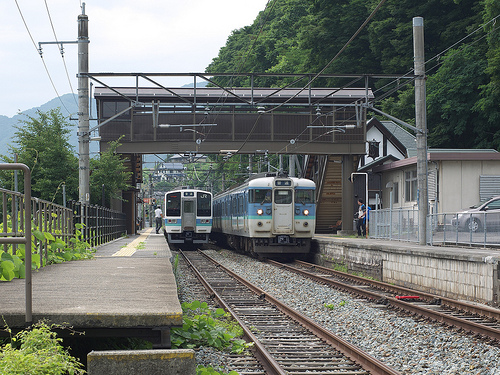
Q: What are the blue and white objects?
A: Train cars.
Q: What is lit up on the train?
A: Lights.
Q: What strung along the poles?
A: Wires.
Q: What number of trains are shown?
A: Two.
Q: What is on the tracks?
A: Trains.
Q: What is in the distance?
A: Mountains.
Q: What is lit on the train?
A: Headlights.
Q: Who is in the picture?
A: Two men.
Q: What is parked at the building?
A: A car.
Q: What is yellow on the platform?
A: A stripe.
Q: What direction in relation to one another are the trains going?
A: Opposite.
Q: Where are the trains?
A: On the track.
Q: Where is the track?
A: On the ground.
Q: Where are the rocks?
A: On the ground.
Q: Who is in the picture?
A: People.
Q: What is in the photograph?
A: Trains.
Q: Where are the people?
A: Train station.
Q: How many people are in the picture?
A: Two.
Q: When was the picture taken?
A: Daytime.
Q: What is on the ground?
A: Tracks.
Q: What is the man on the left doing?
A: Getting on the train.